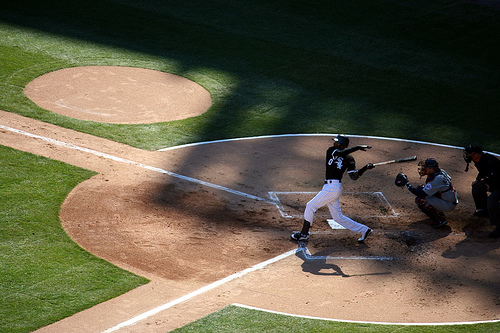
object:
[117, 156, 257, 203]
line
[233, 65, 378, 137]
field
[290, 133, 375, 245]
batter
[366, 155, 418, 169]
bat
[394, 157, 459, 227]
catcher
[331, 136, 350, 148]
helmet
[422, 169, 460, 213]
uniform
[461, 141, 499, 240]
umpire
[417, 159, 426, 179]
mask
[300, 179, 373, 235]
pants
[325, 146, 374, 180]
jersey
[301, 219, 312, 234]
socks